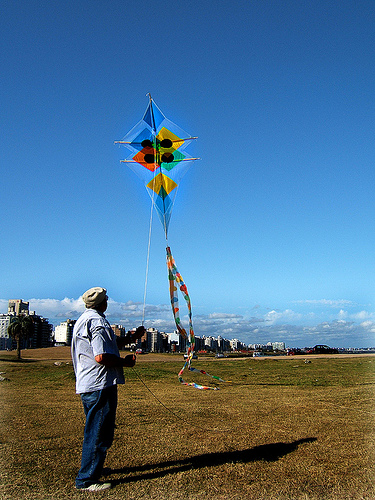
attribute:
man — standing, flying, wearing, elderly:
[62, 287, 141, 495]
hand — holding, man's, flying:
[125, 353, 139, 369]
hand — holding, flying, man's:
[133, 327, 147, 339]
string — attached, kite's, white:
[131, 173, 271, 441]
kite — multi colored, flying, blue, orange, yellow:
[112, 87, 230, 398]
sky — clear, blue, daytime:
[13, 3, 374, 343]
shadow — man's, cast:
[102, 423, 321, 491]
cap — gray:
[82, 283, 109, 305]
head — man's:
[82, 288, 109, 314]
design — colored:
[127, 95, 181, 233]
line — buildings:
[47, 330, 296, 353]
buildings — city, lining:
[51, 319, 295, 357]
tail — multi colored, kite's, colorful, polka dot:
[163, 241, 207, 403]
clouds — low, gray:
[2, 293, 374, 339]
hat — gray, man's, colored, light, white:
[79, 290, 107, 307]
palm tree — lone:
[8, 315, 40, 363]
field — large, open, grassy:
[3, 325, 374, 495]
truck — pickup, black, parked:
[302, 341, 336, 357]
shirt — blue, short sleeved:
[67, 310, 126, 400]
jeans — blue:
[78, 385, 123, 486]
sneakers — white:
[75, 464, 117, 494]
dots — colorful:
[166, 248, 217, 390]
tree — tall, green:
[4, 314, 40, 360]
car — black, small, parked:
[304, 340, 339, 355]